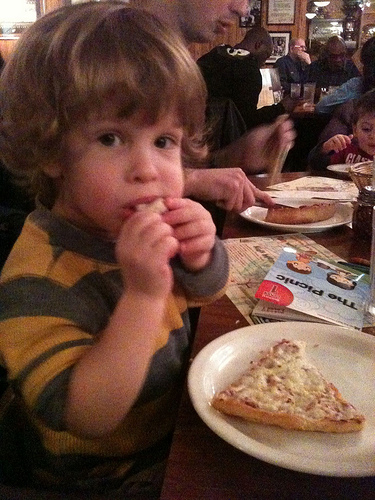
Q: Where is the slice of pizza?
A: On plate.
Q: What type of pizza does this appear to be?
A: Cheese.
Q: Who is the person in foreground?
A: Child.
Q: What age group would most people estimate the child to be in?
A: Toddler.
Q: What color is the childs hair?
A: Brown.